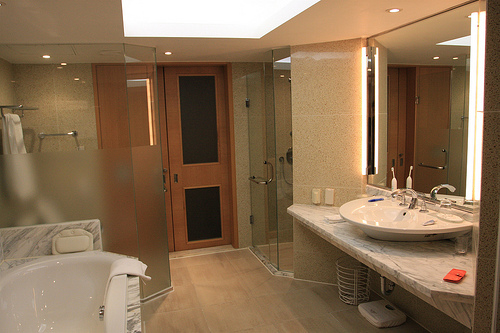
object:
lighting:
[358, 46, 368, 182]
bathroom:
[0, 0, 499, 332]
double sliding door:
[122, 42, 173, 301]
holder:
[389, 201, 398, 206]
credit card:
[441, 268, 469, 283]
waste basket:
[333, 258, 375, 306]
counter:
[287, 203, 475, 306]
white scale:
[355, 298, 408, 329]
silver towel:
[247, 175, 266, 185]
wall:
[291, 35, 359, 282]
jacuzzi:
[0, 249, 133, 333]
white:
[0, 272, 73, 285]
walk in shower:
[0, 46, 158, 290]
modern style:
[287, 170, 478, 253]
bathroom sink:
[340, 190, 473, 246]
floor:
[142, 243, 430, 331]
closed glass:
[122, 43, 173, 298]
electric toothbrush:
[389, 165, 398, 198]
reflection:
[381, 36, 467, 197]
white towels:
[0, 112, 41, 203]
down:
[1, 113, 32, 202]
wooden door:
[166, 67, 237, 250]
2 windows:
[176, 75, 223, 165]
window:
[122, 75, 160, 149]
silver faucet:
[390, 188, 430, 213]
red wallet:
[441, 267, 466, 284]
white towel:
[101, 257, 150, 302]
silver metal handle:
[263, 159, 278, 185]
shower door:
[245, 46, 276, 267]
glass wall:
[0, 42, 143, 303]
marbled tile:
[190, 272, 252, 307]